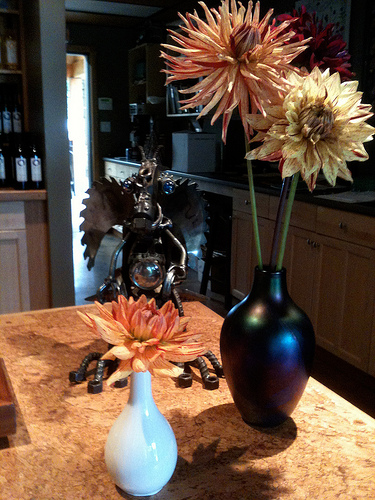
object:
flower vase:
[104, 364, 178, 496]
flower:
[245, 66, 374, 198]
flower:
[158, 1, 313, 143]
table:
[0, 299, 373, 497]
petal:
[147, 351, 184, 378]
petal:
[111, 342, 135, 361]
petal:
[86, 317, 132, 343]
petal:
[163, 341, 207, 363]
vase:
[217, 262, 318, 426]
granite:
[217, 439, 370, 477]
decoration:
[67, 142, 227, 396]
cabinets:
[307, 222, 372, 361]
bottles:
[5, 35, 20, 70]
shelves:
[1, 2, 42, 191]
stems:
[244, 130, 264, 271]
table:
[1, 186, 46, 199]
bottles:
[14, 147, 29, 191]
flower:
[293, 23, 351, 86]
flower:
[76, 291, 208, 384]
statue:
[79, 144, 211, 319]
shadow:
[158, 429, 286, 500]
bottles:
[31, 146, 43, 191]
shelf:
[0, 188, 48, 318]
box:
[172, 131, 217, 173]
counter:
[161, 172, 234, 259]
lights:
[162, 180, 175, 194]